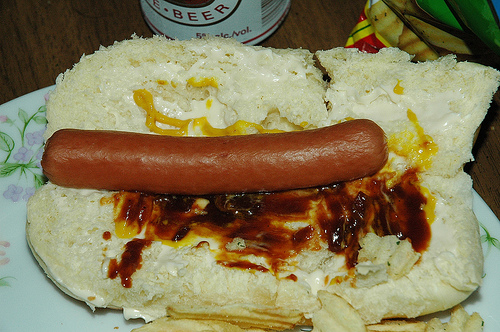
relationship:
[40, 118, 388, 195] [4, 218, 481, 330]
hot dog on plate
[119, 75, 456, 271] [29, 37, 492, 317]
mustard on bun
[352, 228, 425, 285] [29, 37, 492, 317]
chip on bun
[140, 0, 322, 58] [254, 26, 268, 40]
can has part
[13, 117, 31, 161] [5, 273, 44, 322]
flowers on plate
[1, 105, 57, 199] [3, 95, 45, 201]
flowers are on plate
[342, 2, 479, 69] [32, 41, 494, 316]
bag by hot dog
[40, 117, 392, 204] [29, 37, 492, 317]
hot dog in bun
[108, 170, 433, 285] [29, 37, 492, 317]
sauce on bun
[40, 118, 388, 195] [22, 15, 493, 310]
hot dog on a plate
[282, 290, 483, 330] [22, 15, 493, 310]
chips on a plate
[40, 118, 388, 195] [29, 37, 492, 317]
hot dog shorter than bun